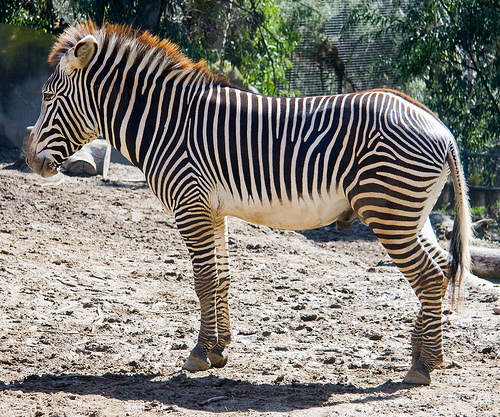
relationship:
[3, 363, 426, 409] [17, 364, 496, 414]
shadow on ground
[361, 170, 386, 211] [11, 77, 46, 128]
ground on rock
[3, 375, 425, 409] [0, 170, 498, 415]
shadow on sand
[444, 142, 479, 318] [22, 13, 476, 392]
tail on zebra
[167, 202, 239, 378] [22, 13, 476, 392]
legs on zebra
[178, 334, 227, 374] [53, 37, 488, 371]
hooves are on zebra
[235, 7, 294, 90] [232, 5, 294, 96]
leaves are on tree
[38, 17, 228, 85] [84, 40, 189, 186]
mane on neck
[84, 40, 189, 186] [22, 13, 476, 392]
neck on zebra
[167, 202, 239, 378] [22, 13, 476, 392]
legs are on zebra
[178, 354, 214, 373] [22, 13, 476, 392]
hooves on zebra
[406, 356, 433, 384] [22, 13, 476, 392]
hoof on zebra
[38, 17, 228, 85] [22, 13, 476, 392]
mane on zebra